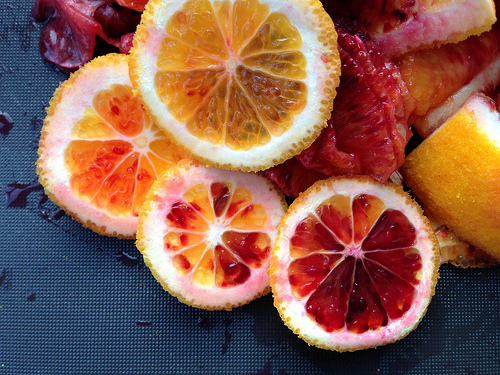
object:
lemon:
[128, 0, 343, 173]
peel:
[198, 147, 278, 172]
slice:
[236, 62, 319, 140]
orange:
[267, 175, 442, 353]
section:
[288, 222, 354, 263]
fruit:
[263, 25, 416, 199]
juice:
[5, 179, 45, 206]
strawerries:
[27, 0, 148, 72]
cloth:
[0, 0, 177, 374]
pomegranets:
[360, 0, 498, 55]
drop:
[0, 111, 16, 136]